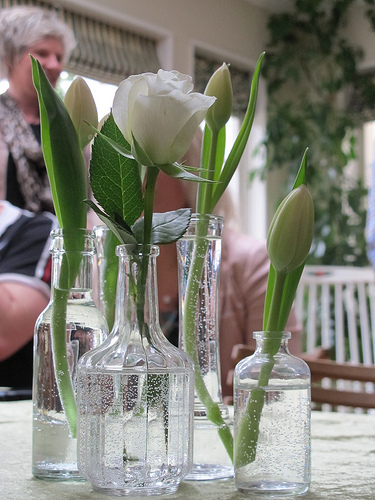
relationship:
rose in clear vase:
[78, 69, 223, 335] [74, 241, 194, 494]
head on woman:
[0, 5, 75, 91] [4, 13, 99, 169]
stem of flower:
[133, 163, 159, 338] [112, 65, 215, 168]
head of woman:
[7, 20, 69, 91] [6, 13, 55, 169]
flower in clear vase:
[112, 65, 215, 168] [74, 241, 194, 494]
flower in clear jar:
[112, 65, 215, 168] [231, 329, 312, 498]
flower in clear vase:
[112, 65, 215, 168] [174, 211, 234, 481]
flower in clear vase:
[112, 65, 215, 168] [32, 228, 109, 481]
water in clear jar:
[232, 380, 312, 491] [231, 329, 312, 498]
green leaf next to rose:
[88, 104, 138, 225] [112, 68, 216, 163]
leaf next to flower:
[130, 207, 190, 242] [263, 179, 316, 282]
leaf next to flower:
[28, 54, 88, 290] [201, 61, 234, 134]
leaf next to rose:
[212, 52, 265, 207] [62, 75, 97, 148]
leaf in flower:
[212, 56, 260, 207] [201, 54, 235, 135]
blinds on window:
[83, 30, 152, 68] [81, 27, 120, 117]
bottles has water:
[22, 209, 323, 498] [167, 220, 244, 401]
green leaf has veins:
[88, 104, 138, 225] [87, 106, 144, 219]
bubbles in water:
[259, 400, 304, 473] [234, 384, 310, 498]